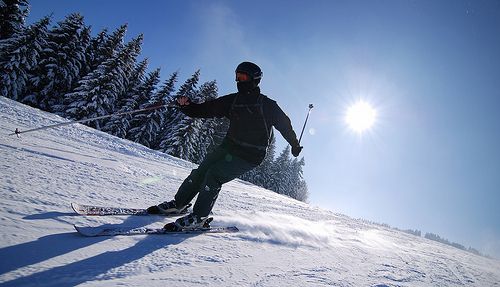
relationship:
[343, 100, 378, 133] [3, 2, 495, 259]
sun in sky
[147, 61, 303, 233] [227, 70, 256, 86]
man wearing goggles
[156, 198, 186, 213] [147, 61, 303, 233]
ski boot on man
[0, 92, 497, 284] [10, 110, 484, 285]
snow on ground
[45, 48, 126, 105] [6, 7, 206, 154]
snow on trees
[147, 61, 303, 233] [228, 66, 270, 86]
man wearing goggles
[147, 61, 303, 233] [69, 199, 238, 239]
man wearing skis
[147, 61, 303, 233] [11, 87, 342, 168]
man holding poles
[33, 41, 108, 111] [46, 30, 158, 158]
snow on trees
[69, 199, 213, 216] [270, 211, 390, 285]
ski covered with snow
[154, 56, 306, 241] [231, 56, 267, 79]
man wearing helmet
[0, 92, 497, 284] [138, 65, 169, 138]
snow covered trees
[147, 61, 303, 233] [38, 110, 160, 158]
man holds pole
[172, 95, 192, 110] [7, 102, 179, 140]
hand holds pole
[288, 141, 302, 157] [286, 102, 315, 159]
hand holds poles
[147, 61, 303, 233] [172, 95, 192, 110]
man has hand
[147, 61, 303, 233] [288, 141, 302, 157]
man has hand